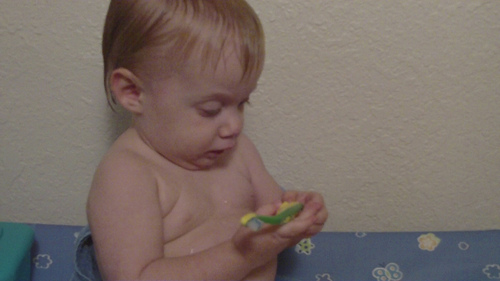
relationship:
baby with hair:
[80, 0, 310, 277] [62, 15, 292, 83]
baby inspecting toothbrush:
[80, 0, 310, 277] [233, 198, 310, 235]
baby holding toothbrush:
[80, 0, 310, 277] [237, 193, 303, 230]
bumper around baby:
[28, 222, 495, 278] [66, 1, 408, 279]